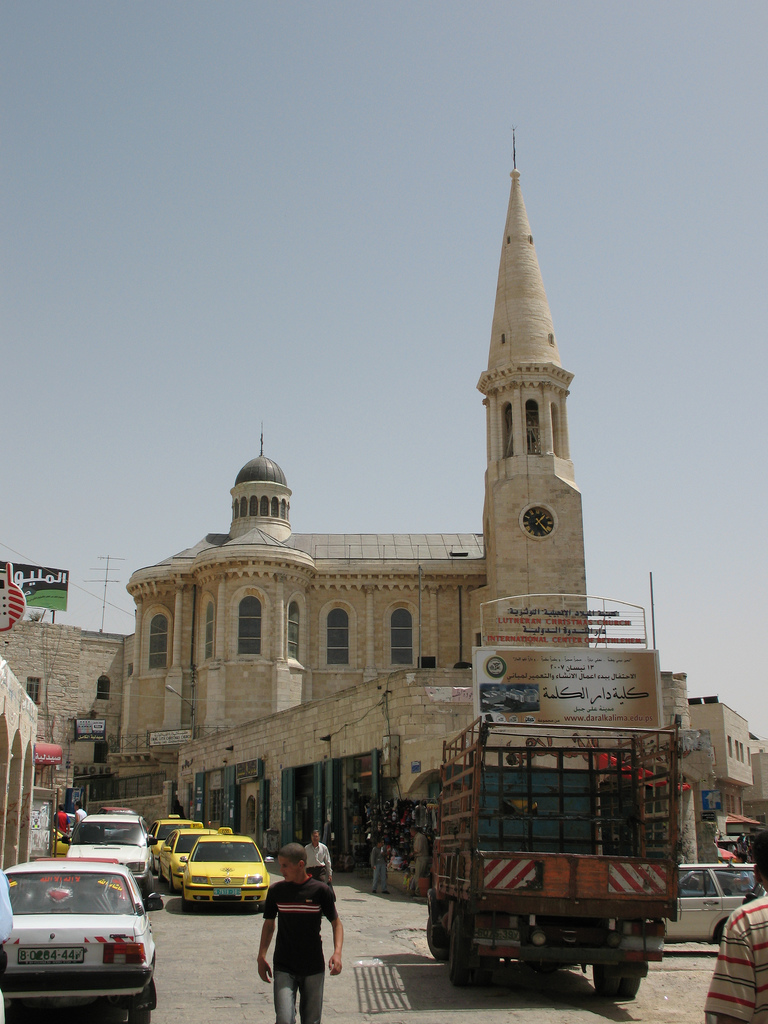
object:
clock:
[519, 503, 559, 542]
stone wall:
[488, 469, 588, 644]